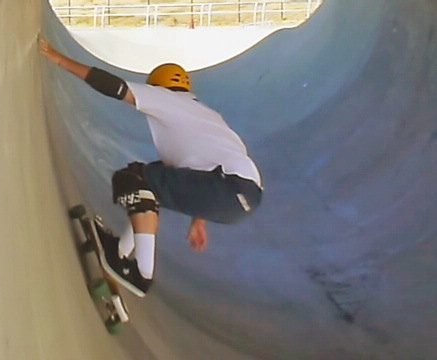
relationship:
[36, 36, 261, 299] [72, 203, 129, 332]
man riding skateboard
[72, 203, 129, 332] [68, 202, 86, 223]
skateboard has wheel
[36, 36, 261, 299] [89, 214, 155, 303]
man wearing shoes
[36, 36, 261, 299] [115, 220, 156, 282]
man wearing socks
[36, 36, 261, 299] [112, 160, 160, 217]
man wearing knee pads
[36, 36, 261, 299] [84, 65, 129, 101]
man wearing elbow pads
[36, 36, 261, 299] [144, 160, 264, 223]
man wearing shorts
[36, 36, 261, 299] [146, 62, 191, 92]
man wearing helmet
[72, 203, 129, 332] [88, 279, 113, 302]
skateboard has wheel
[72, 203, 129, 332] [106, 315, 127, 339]
skateboard has wheel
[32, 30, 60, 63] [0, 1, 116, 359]
hand on wall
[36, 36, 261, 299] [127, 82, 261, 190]
man wearing shirt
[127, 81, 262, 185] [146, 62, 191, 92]
man wearing helmet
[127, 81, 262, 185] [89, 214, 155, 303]
man wearing shoes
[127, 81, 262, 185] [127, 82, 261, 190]
man wearing shirt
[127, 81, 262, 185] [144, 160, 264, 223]
man wearing shorts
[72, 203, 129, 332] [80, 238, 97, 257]
skateboard has wheel